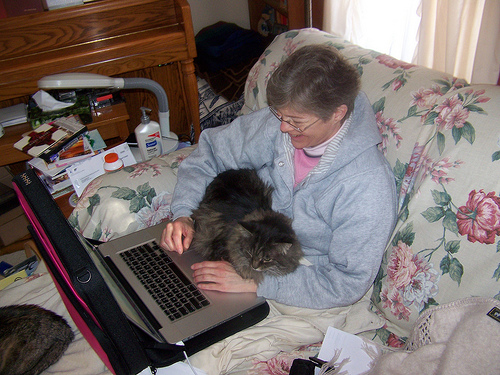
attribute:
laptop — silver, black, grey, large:
[36, 192, 257, 350]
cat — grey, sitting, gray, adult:
[200, 166, 297, 281]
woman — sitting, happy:
[255, 38, 393, 298]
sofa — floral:
[82, 34, 497, 337]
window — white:
[317, 0, 495, 96]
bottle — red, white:
[96, 150, 128, 183]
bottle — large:
[135, 111, 163, 160]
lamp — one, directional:
[35, 67, 180, 161]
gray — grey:
[320, 142, 381, 275]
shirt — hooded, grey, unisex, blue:
[229, 117, 396, 264]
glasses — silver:
[263, 105, 312, 138]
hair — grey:
[260, 43, 358, 125]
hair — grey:
[200, 185, 282, 257]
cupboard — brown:
[250, 2, 323, 37]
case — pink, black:
[13, 171, 140, 369]